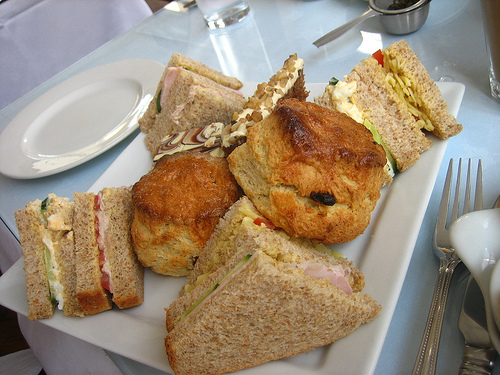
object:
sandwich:
[146, 75, 244, 157]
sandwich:
[156, 195, 365, 332]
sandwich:
[367, 39, 463, 149]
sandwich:
[137, 53, 243, 148]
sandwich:
[75, 188, 146, 317]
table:
[0, 0, 499, 374]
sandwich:
[161, 236, 380, 374]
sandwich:
[312, 71, 420, 185]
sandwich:
[14, 190, 83, 322]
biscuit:
[224, 98, 387, 244]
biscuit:
[130, 150, 236, 277]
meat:
[93, 193, 109, 291]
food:
[11, 38, 460, 374]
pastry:
[182, 209, 259, 297]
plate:
[0, 57, 465, 374]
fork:
[405, 158, 483, 374]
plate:
[0, 57, 167, 180]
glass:
[480, 0, 499, 99]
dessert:
[149, 121, 224, 169]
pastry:
[386, 72, 436, 133]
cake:
[222, 52, 310, 153]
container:
[312, 0, 433, 48]